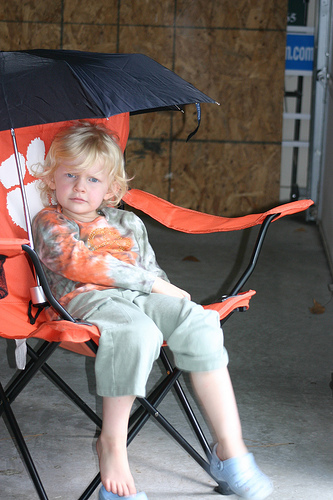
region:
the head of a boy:
[42, 149, 145, 216]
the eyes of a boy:
[53, 169, 116, 193]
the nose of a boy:
[60, 177, 93, 199]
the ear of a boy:
[46, 168, 61, 194]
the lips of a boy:
[65, 189, 108, 209]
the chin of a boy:
[60, 201, 101, 217]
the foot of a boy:
[94, 426, 146, 493]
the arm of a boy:
[19, 229, 204, 325]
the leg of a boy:
[69, 284, 192, 474]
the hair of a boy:
[34, 116, 142, 196]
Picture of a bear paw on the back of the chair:
[0, 136, 59, 237]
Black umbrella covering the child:
[0, 35, 226, 311]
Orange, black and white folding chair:
[0, 109, 312, 499]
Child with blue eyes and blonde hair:
[33, 125, 134, 214]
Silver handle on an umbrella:
[27, 284, 50, 307]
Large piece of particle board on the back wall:
[0, 0, 293, 231]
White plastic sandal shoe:
[207, 440, 274, 499]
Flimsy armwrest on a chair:
[121, 183, 314, 236]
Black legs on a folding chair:
[1, 357, 240, 498]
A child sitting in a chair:
[1, 106, 316, 497]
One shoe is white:
[201, 440, 275, 498]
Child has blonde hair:
[33, 117, 130, 217]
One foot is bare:
[89, 432, 142, 498]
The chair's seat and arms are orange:
[1, 109, 317, 358]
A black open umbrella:
[2, 41, 231, 291]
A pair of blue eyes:
[60, 167, 102, 186]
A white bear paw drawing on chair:
[0, 133, 57, 237]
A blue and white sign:
[280, 33, 318, 78]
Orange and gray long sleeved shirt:
[27, 208, 171, 319]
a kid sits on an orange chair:
[2, 99, 315, 497]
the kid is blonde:
[20, 111, 154, 283]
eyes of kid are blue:
[61, 169, 103, 185]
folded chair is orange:
[3, 101, 312, 493]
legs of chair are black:
[4, 350, 209, 498]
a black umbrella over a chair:
[2, 36, 319, 356]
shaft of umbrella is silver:
[5, 127, 44, 299]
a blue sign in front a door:
[284, 22, 320, 77]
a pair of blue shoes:
[91, 440, 281, 498]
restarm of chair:
[129, 182, 317, 235]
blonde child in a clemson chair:
[36, 121, 241, 481]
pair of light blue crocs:
[75, 441, 274, 499]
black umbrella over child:
[5, 49, 206, 135]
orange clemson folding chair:
[1, 123, 137, 284]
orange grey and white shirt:
[39, 206, 166, 304]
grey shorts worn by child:
[64, 291, 228, 390]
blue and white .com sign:
[276, 26, 320, 78]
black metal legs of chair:
[10, 329, 218, 496]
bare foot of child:
[84, 404, 137, 498]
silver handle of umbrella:
[4, 131, 46, 311]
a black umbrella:
[0, 45, 220, 307]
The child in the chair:
[31, 122, 274, 499]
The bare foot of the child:
[96, 436, 135, 498]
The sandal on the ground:
[99, 482, 145, 498]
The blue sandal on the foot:
[207, 441, 274, 499]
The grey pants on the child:
[65, 288, 230, 396]